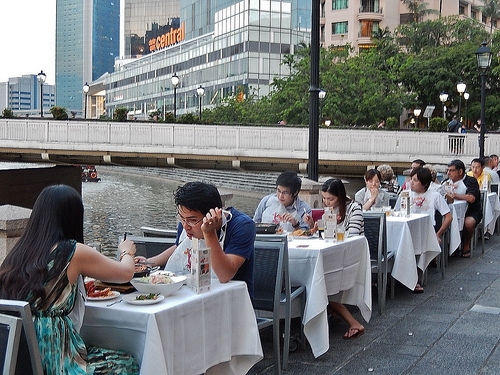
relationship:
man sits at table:
[128, 172, 261, 309] [71, 258, 270, 374]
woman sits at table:
[3, 171, 141, 374] [71, 258, 270, 374]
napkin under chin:
[166, 240, 224, 284] [185, 236, 203, 243]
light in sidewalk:
[473, 33, 500, 155] [444, 215, 500, 371]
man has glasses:
[128, 172, 261, 309] [168, 207, 206, 231]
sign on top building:
[139, 19, 193, 56] [91, 2, 308, 109]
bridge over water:
[3, 111, 493, 169] [14, 174, 175, 226]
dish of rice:
[127, 266, 191, 300] [135, 267, 177, 287]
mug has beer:
[334, 222, 352, 244] [332, 232, 345, 243]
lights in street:
[25, 41, 496, 133] [361, 240, 499, 365]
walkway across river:
[3, 111, 493, 169] [14, 174, 175, 226]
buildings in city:
[5, 1, 476, 109] [0, 2, 499, 370]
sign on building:
[139, 19, 193, 56] [91, 2, 308, 109]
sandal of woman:
[341, 325, 368, 342] [310, 171, 377, 350]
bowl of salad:
[122, 291, 173, 309] [131, 289, 160, 303]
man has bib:
[128, 172, 261, 309] [166, 240, 224, 284]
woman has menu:
[310, 171, 377, 350] [310, 203, 327, 225]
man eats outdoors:
[128, 172, 261, 309] [12, 146, 500, 368]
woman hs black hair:
[3, 171, 141, 374] [2, 179, 101, 324]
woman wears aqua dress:
[3, 171, 141, 374] [6, 236, 143, 374]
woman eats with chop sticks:
[3, 171, 141, 374] [118, 228, 130, 246]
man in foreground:
[128, 172, 261, 309] [1, 161, 273, 375]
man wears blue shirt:
[128, 172, 261, 309] [170, 212, 260, 294]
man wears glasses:
[128, 172, 261, 309] [168, 207, 206, 231]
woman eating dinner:
[3, 171, 141, 374] [83, 249, 188, 311]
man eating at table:
[128, 172, 261, 309] [71, 258, 270, 374]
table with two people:
[71, 258, 270, 374] [1, 161, 273, 375]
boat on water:
[75, 160, 106, 188] [14, 174, 175, 226]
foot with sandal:
[338, 316, 369, 340] [341, 325, 368, 344]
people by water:
[12, 146, 500, 368] [14, 174, 175, 226]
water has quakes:
[14, 174, 175, 226] [81, 173, 174, 224]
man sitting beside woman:
[252, 171, 303, 232] [310, 171, 377, 350]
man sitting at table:
[252, 171, 303, 232] [254, 224, 370, 366]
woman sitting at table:
[310, 171, 377, 350] [254, 224, 370, 366]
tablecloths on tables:
[81, 185, 497, 372] [121, 226, 499, 375]